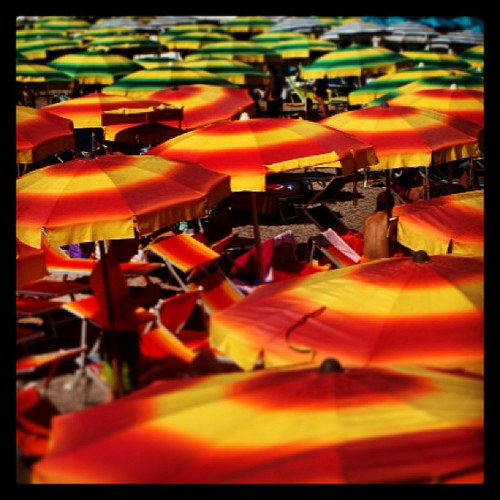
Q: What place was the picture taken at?
A: It was taken at the beach.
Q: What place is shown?
A: It is a beach.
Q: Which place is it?
A: It is a beach.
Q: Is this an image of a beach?
A: Yes, it is showing a beach.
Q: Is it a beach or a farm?
A: It is a beach.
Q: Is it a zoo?
A: No, it is a beach.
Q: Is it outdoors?
A: Yes, it is outdoors.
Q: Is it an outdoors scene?
A: Yes, it is outdoors.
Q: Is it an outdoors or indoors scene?
A: It is outdoors.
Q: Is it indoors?
A: No, it is outdoors.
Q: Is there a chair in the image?
A: Yes, there is a chair.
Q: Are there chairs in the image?
A: Yes, there is a chair.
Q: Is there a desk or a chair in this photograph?
A: Yes, there is a chair.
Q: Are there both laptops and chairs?
A: No, there is a chair but no laptops.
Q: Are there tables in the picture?
A: No, there are no tables.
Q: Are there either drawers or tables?
A: No, there are no tables or drawers.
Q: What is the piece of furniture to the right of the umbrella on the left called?
A: The piece of furniture is a chair.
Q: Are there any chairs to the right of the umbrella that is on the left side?
A: Yes, there is a chair to the right of the umbrella.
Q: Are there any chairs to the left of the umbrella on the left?
A: No, the chair is to the right of the umbrella.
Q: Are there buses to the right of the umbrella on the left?
A: No, there is a chair to the right of the umbrella.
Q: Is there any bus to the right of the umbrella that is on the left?
A: No, there is a chair to the right of the umbrella.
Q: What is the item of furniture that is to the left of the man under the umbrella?
A: The piece of furniture is a chair.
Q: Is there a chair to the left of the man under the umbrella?
A: Yes, there is a chair to the left of the man.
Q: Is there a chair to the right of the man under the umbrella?
A: No, the chair is to the left of the man.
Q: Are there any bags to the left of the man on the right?
A: No, there is a chair to the left of the man.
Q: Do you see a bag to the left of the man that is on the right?
A: No, there is a chair to the left of the man.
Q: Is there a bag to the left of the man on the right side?
A: No, there is a chair to the left of the man.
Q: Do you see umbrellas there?
A: Yes, there is an umbrella.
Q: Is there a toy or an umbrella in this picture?
A: Yes, there is an umbrella.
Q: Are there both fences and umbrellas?
A: No, there is an umbrella but no fences.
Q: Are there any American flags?
A: No, there are no American flags.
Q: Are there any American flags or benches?
A: No, there are no American flags or benches.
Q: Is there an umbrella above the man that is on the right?
A: Yes, there is an umbrella above the man.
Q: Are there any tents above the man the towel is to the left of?
A: No, there is an umbrella above the man.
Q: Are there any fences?
A: No, there are no fences.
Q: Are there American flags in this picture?
A: No, there are no American flags.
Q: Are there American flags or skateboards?
A: No, there are no American flags or skateboards.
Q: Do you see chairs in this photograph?
A: Yes, there is a chair.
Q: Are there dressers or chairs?
A: Yes, there is a chair.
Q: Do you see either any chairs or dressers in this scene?
A: Yes, there is a chair.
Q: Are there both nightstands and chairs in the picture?
A: No, there is a chair but no nightstands.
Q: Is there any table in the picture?
A: No, there are no tables.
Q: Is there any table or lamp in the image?
A: No, there are no tables or lamps.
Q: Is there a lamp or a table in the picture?
A: No, there are no tables or lamps.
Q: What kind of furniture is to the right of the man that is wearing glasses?
A: The piece of furniture is a chair.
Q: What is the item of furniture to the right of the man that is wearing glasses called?
A: The piece of furniture is a chair.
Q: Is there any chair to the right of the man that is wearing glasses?
A: Yes, there is a chair to the right of the man.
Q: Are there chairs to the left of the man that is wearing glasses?
A: No, the chair is to the right of the man.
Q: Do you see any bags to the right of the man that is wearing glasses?
A: No, there is a chair to the right of the man.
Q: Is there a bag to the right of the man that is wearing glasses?
A: No, there is a chair to the right of the man.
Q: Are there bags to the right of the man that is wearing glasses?
A: No, there is a chair to the right of the man.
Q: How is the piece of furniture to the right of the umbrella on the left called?
A: The piece of furniture is a chair.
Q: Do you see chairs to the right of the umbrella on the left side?
A: Yes, there is a chair to the right of the umbrella.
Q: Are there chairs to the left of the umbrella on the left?
A: No, the chair is to the right of the umbrella.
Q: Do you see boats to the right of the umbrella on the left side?
A: No, there is a chair to the right of the umbrella.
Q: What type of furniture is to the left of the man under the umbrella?
A: The piece of furniture is a chair.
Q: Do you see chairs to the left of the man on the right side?
A: Yes, there is a chair to the left of the man.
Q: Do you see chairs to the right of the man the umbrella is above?
A: No, the chair is to the left of the man.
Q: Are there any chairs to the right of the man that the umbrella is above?
A: No, the chair is to the left of the man.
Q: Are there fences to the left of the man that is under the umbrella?
A: No, there is a chair to the left of the man.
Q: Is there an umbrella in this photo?
A: Yes, there is an umbrella.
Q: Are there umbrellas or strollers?
A: Yes, there is an umbrella.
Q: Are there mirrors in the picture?
A: No, there are no mirrors.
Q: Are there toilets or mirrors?
A: No, there are no mirrors or toilets.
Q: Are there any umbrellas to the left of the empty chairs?
A: Yes, there is an umbrella to the left of the chairs.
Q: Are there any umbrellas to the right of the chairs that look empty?
A: No, the umbrella is to the left of the chairs.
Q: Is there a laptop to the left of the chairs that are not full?
A: No, there is an umbrella to the left of the chairs.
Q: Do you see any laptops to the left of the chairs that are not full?
A: No, there is an umbrella to the left of the chairs.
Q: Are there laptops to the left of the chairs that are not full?
A: No, there is an umbrella to the left of the chairs.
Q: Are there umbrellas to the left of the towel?
A: Yes, there is an umbrella to the left of the towel.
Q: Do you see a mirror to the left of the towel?
A: No, there is an umbrella to the left of the towel.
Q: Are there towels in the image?
A: Yes, there is a towel.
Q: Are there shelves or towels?
A: Yes, there is a towel.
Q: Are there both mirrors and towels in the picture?
A: No, there is a towel but no mirrors.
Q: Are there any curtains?
A: No, there are no curtains.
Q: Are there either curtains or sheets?
A: No, there are no curtains or sheets.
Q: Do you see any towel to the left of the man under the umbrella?
A: Yes, there is a towel to the left of the man.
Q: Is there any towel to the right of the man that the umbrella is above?
A: No, the towel is to the left of the man.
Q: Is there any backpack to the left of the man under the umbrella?
A: No, there is a towel to the left of the man.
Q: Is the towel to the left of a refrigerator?
A: No, the towel is to the left of a man.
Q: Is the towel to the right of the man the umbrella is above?
A: No, the towel is to the left of the man.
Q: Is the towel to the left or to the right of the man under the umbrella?
A: The towel is to the left of the man.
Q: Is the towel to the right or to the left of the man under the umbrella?
A: The towel is to the left of the man.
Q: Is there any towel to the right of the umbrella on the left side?
A: Yes, there is a towel to the right of the umbrella.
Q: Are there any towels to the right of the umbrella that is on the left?
A: Yes, there is a towel to the right of the umbrella.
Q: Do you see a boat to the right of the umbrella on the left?
A: No, there is a towel to the right of the umbrella.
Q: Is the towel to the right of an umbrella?
A: Yes, the towel is to the right of an umbrella.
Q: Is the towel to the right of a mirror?
A: No, the towel is to the right of an umbrella.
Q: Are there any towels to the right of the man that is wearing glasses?
A: Yes, there is a towel to the right of the man.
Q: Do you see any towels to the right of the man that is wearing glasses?
A: Yes, there is a towel to the right of the man.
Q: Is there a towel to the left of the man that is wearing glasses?
A: No, the towel is to the right of the man.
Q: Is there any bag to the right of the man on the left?
A: No, there is a towel to the right of the man.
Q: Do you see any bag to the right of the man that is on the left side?
A: No, there is a towel to the right of the man.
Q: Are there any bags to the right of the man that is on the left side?
A: No, there is a towel to the right of the man.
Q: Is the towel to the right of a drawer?
A: No, the towel is to the right of the man.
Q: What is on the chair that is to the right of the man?
A: The towel is on the chair.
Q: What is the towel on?
A: The towel is on the chair.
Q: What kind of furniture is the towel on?
A: The towel is on the chair.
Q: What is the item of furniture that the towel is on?
A: The piece of furniture is a chair.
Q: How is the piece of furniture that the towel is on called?
A: The piece of furniture is a chair.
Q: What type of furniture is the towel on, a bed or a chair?
A: The towel is on a chair.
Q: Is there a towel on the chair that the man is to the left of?
A: Yes, there is a towel on the chair.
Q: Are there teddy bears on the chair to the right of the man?
A: No, there is a towel on the chair.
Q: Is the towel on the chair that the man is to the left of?
A: Yes, the towel is on the chair.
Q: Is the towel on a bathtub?
A: No, the towel is on the chair.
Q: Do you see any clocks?
A: No, there are no clocks.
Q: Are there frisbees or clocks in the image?
A: No, there are no clocks or frisbees.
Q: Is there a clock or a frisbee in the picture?
A: No, there are no clocks or frisbees.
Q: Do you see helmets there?
A: No, there are no helmets.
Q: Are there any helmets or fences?
A: No, there are no helmets or fences.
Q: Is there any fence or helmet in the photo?
A: No, there are no helmets or fences.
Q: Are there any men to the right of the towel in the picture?
A: Yes, there is a man to the right of the towel.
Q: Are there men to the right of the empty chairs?
A: Yes, there is a man to the right of the chairs.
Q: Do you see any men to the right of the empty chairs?
A: Yes, there is a man to the right of the chairs.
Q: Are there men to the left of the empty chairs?
A: No, the man is to the right of the chairs.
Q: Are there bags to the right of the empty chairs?
A: No, there is a man to the right of the chairs.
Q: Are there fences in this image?
A: No, there are no fences.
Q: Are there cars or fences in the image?
A: No, there are no fences or cars.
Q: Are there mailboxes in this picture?
A: No, there are no mailboxes.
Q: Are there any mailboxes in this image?
A: No, there are no mailboxes.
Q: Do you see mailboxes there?
A: No, there are no mailboxes.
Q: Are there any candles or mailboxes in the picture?
A: No, there are no mailboxes or candles.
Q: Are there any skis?
A: No, there are no skis.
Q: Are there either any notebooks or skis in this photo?
A: No, there are no skis or notebooks.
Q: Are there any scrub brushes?
A: No, there are no scrub brushes.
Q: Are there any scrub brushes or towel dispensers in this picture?
A: No, there are no scrub brushes or towel dispensers.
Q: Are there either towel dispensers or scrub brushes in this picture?
A: No, there are no scrub brushes or towel dispensers.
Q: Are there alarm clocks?
A: No, there are no alarm clocks.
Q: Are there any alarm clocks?
A: No, there are no alarm clocks.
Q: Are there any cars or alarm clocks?
A: No, there are no alarm clocks or cars.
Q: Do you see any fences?
A: No, there are no fences.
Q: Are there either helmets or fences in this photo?
A: No, there are no fences or helmets.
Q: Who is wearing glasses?
A: The man is wearing glasses.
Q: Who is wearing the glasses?
A: The man is wearing glasses.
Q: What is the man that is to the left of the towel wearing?
A: The man is wearing glasses.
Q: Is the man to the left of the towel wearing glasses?
A: Yes, the man is wearing glasses.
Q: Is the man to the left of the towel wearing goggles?
A: No, the man is wearing glasses.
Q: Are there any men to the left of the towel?
A: Yes, there is a man to the left of the towel.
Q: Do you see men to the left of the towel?
A: Yes, there is a man to the left of the towel.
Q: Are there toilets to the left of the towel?
A: No, there is a man to the left of the towel.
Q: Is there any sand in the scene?
A: Yes, there is sand.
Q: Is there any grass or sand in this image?
A: Yes, there is sand.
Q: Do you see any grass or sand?
A: Yes, there is sand.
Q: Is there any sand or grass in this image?
A: Yes, there is sand.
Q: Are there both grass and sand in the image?
A: No, there is sand but no grass.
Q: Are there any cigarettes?
A: No, there are no cigarettes.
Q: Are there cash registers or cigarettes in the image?
A: No, there are no cigarettes or cash registers.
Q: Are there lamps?
A: No, there are no lamps.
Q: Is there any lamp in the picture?
A: No, there are no lamps.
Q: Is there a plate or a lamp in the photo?
A: No, there are no lamps or plates.